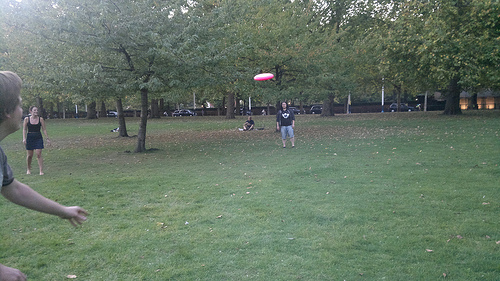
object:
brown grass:
[156, 131, 235, 139]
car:
[388, 101, 415, 112]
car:
[172, 109, 197, 118]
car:
[310, 104, 323, 114]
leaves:
[392, 147, 397, 150]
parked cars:
[288, 106, 301, 114]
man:
[243, 116, 255, 131]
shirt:
[276, 108, 295, 126]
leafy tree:
[60, 0, 205, 152]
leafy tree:
[288, 0, 374, 116]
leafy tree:
[402, 0, 496, 113]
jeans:
[280, 125, 294, 139]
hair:
[0, 70, 23, 122]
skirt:
[25, 132, 44, 149]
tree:
[0, 6, 53, 119]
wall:
[354, 104, 381, 112]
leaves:
[344, 176, 347, 179]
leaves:
[426, 248, 433, 252]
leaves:
[184, 221, 189, 225]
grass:
[107, 156, 500, 281]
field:
[0, 118, 495, 281]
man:
[0, 70, 90, 281]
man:
[276, 102, 295, 148]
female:
[22, 106, 50, 176]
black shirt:
[26, 116, 41, 132]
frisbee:
[253, 73, 274, 82]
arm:
[0, 147, 65, 215]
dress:
[26, 116, 44, 150]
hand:
[62, 206, 89, 227]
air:
[229, 67, 251, 99]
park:
[21, 0, 494, 281]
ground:
[171, 148, 263, 279]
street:
[194, 114, 223, 117]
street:
[310, 111, 388, 115]